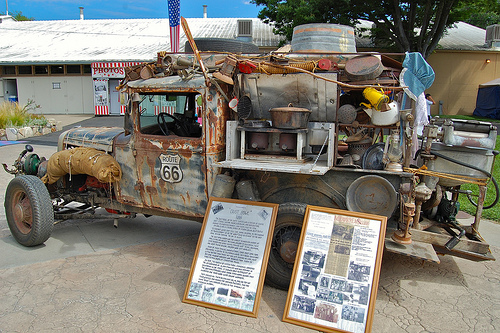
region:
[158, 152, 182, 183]
white sign on truck that says Route 66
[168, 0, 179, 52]
American flag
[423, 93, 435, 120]
man putting his hand to his face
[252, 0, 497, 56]
tree with green leaves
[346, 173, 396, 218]
gray metal pan on the side of the truck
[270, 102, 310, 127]
rusted metal pot with lid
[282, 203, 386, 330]
framed collage with newspaper clipping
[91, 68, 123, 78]
white sign that says PHOTOS in red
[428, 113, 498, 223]
patch of green grass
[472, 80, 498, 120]
part of blue tent area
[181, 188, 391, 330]
two posters leaning against a truck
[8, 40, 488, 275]
a truck parked on the street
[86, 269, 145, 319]
grey concrete surface of the road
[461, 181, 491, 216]
green grass of the ground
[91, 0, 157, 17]
clear blue skies over the building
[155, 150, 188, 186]
white and black logo on the truck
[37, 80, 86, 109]
white wall of the building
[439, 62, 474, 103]
tan stucco wall of a building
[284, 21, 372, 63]
grey metal bucket on the top of the truck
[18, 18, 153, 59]
white roof of the building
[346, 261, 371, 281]
old photo in frame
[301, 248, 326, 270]
old photo in frame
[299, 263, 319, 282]
old photo in frame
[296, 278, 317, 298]
old photo in frame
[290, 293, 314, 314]
old photo in frame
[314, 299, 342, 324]
old photo in frame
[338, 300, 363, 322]
old photo in frame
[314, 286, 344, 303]
old photo in frame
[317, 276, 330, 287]
old photo in frame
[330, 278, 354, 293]
old photo in frame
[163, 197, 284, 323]
sign in wooden frame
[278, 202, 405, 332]
sign in wooden frame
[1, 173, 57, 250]
tire of an old truck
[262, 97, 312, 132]
old rusty pot with lid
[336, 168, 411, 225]
old bucket on a truck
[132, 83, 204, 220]
door of a rusty truck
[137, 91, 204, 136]
window of a truck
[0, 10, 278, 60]
roof of a building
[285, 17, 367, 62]
wash basin on top of truck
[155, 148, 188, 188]
logo painted on a truck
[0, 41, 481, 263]
a parked antique truck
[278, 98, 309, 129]
a metal pot on a truck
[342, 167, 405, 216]
a tin tub on a truck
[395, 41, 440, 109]
a blue apron hanging on a truck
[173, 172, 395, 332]
two signs leaning on a truck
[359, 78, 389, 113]
a yellow coffee pot on a truck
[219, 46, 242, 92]
a lantern on a truck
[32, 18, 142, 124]
a building with a white roof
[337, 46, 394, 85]
a iron frying pan on a truck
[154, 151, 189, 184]
a black and white sign on a truck door